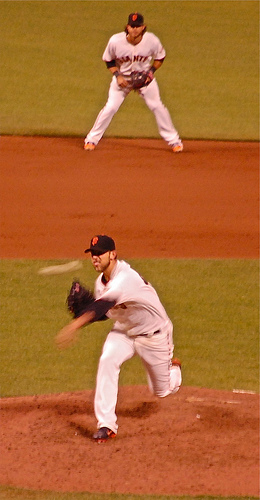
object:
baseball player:
[83, 12, 185, 153]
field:
[0, 0, 260, 500]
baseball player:
[51, 232, 184, 441]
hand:
[117, 74, 128, 89]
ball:
[34, 258, 81, 274]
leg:
[143, 339, 183, 399]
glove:
[67, 282, 95, 317]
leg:
[143, 77, 178, 145]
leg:
[85, 77, 128, 146]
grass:
[0, 0, 260, 139]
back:
[138, 275, 150, 293]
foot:
[91, 426, 117, 444]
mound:
[0, 383, 260, 499]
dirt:
[159, 439, 173, 465]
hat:
[128, 13, 144, 26]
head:
[126, 13, 145, 37]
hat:
[84, 234, 116, 254]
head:
[90, 235, 117, 273]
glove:
[132, 71, 152, 90]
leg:
[94, 330, 133, 433]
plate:
[189, 394, 249, 413]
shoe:
[93, 421, 118, 446]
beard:
[102, 261, 111, 271]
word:
[116, 55, 148, 65]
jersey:
[102, 32, 166, 80]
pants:
[84, 77, 181, 146]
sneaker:
[83, 141, 96, 151]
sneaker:
[171, 141, 183, 153]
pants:
[92, 328, 181, 432]